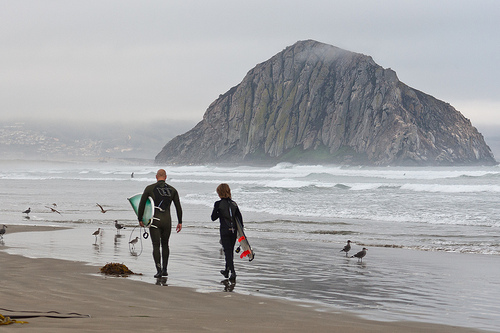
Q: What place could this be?
A: It is a beach.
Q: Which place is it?
A: It is a beach.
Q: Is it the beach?
A: Yes, it is the beach.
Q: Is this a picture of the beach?
A: Yes, it is showing the beach.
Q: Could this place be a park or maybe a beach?
A: It is a beach.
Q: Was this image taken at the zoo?
A: No, the picture was taken in the beach.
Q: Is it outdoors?
A: Yes, it is outdoors.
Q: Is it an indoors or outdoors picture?
A: It is outdoors.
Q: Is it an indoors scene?
A: No, it is outdoors.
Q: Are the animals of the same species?
A: Yes, all the animals are birds.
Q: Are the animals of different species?
A: No, all the animals are birds.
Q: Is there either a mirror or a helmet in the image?
A: No, there are no helmets or mirrors.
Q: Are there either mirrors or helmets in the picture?
A: No, there are no helmets or mirrors.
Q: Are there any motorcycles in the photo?
A: No, there are no motorcycles.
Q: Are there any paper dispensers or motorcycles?
A: No, there are no motorcycles or paper dispensers.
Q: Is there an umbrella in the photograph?
A: No, there are no umbrellas.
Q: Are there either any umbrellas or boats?
A: No, there are no umbrellas or boats.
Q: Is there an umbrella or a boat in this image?
A: No, there are no umbrellas or boats.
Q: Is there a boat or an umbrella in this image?
A: No, there are no umbrellas or boats.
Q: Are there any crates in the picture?
A: No, there are no crates.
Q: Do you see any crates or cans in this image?
A: No, there are no crates or cans.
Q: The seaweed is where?
A: The seaweed is on the beach.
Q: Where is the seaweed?
A: The seaweed is on the beach.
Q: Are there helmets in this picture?
A: No, there are no helmets.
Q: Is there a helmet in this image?
A: No, there are no helmets.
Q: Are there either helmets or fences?
A: No, there are no helmets or fences.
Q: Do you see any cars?
A: No, there are no cars.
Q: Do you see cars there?
A: No, there are no cars.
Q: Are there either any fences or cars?
A: No, there are no cars or fences.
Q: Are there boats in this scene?
A: No, there are no boats.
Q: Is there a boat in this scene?
A: No, there are no boats.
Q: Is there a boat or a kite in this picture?
A: No, there are no boats or kites.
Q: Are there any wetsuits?
A: Yes, there is a wetsuit.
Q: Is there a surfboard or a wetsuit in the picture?
A: Yes, there is a wetsuit.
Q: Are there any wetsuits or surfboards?
A: Yes, there is a wetsuit.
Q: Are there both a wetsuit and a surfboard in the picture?
A: Yes, there are both a wetsuit and a surfboard.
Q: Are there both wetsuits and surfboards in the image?
A: Yes, there are both a wetsuit and a surfboard.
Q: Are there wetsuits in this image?
A: Yes, there is a wetsuit.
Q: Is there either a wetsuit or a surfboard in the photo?
A: Yes, there is a wetsuit.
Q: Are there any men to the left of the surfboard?
A: Yes, there is a man to the left of the surfboard.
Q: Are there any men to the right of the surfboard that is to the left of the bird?
A: No, the man is to the left of the surfboard.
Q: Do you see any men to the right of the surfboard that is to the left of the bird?
A: No, the man is to the left of the surfboard.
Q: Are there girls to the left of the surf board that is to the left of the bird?
A: No, there is a man to the left of the surf board.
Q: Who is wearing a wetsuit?
A: The man is wearing a wetsuit.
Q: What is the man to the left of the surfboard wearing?
A: The man is wearing a wetsuit.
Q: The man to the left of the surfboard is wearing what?
A: The man is wearing a wetsuit.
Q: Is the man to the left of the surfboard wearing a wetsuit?
A: Yes, the man is wearing a wetsuit.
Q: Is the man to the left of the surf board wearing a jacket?
A: No, the man is wearing a wetsuit.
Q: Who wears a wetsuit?
A: The man wears a wetsuit.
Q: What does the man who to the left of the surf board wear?
A: The man wears a wetsuit.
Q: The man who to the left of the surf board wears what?
A: The man wears a wetsuit.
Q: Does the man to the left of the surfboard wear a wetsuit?
A: Yes, the man wears a wetsuit.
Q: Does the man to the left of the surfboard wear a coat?
A: No, the man wears a wetsuit.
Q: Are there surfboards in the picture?
A: Yes, there is a surfboard.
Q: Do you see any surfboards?
A: Yes, there is a surfboard.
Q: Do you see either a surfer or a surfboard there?
A: Yes, there is a surfboard.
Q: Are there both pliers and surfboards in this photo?
A: No, there is a surfboard but no pliers.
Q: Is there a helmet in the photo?
A: No, there are no helmets.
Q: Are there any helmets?
A: No, there are no helmets.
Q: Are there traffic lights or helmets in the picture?
A: No, there are no helmets or traffic lights.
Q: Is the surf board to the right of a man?
A: Yes, the surf board is to the right of a man.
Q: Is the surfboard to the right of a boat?
A: No, the surfboard is to the right of a man.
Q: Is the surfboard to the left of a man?
A: No, the surfboard is to the right of a man.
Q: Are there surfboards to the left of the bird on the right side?
A: Yes, there is a surfboard to the left of the bird.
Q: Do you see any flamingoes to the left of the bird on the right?
A: No, there is a surfboard to the left of the bird.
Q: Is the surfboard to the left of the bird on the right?
A: Yes, the surfboard is to the left of the bird.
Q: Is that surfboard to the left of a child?
A: No, the surfboard is to the left of the bird.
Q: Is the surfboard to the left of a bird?
A: Yes, the surfboard is to the left of a bird.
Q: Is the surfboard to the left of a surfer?
A: No, the surfboard is to the left of a bird.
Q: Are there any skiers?
A: No, there are no skiers.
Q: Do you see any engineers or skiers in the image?
A: No, there are no skiers or engineers.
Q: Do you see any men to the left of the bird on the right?
A: Yes, there is a man to the left of the bird.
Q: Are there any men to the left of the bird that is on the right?
A: Yes, there is a man to the left of the bird.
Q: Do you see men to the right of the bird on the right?
A: No, the man is to the left of the bird.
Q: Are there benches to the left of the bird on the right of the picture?
A: No, there is a man to the left of the bird.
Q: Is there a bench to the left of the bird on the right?
A: No, there is a man to the left of the bird.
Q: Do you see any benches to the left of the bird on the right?
A: No, there is a man to the left of the bird.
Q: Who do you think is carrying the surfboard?
A: The man is carrying the surfboard.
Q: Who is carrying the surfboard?
A: The man is carrying the surfboard.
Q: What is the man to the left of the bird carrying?
A: The man is carrying a surfboard.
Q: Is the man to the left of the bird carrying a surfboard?
A: Yes, the man is carrying a surfboard.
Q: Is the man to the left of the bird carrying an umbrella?
A: No, the man is carrying a surfboard.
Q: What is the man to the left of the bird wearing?
A: The man is wearing a wetsuit.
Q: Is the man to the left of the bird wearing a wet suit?
A: Yes, the man is wearing a wet suit.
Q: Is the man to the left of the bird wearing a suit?
A: No, the man is wearing a wet suit.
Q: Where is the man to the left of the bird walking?
A: The man is walking on the shore.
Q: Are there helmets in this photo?
A: No, there are no helmets.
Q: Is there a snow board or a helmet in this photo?
A: No, there are no helmets or snowboards.